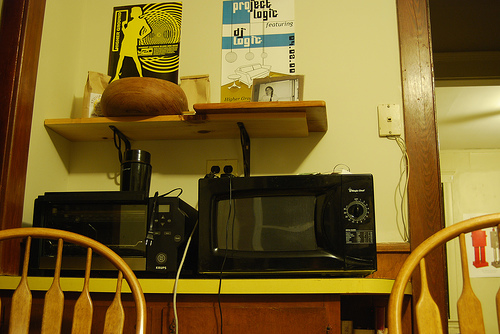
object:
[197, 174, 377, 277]
microwave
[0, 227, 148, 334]
chair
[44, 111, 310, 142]
shelf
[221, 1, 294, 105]
sign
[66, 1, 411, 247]
wall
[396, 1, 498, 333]
door frame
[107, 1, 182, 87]
picture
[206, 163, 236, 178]
outlet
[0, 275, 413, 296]
counter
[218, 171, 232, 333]
cord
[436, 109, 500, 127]
shadow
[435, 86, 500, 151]
ceiling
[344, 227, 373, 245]
writing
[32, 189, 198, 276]
toaster oven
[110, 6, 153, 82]
female figure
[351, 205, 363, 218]
dial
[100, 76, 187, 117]
bowl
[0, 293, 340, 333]
cabinets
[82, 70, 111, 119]
paper bag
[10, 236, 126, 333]
slats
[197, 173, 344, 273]
door